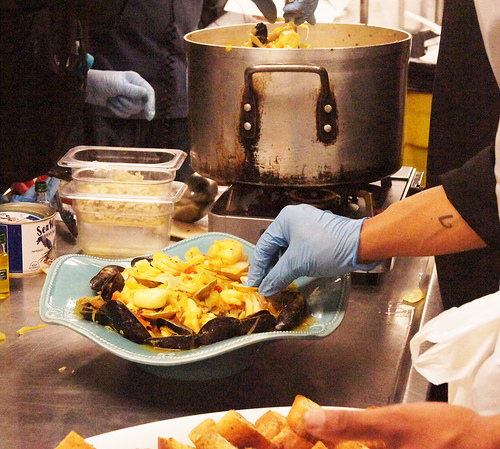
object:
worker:
[254, 139, 499, 448]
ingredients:
[0, 202, 57, 279]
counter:
[0, 184, 435, 444]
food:
[97, 203, 144, 226]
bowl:
[37, 230, 352, 382]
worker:
[245, 0, 499, 444]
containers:
[59, 144, 189, 194]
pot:
[178, 18, 430, 188]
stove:
[206, 164, 423, 273]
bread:
[157, 435, 196, 447]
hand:
[252, 0, 317, 26]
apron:
[408, 291, 499, 418]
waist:
[432, 251, 499, 308]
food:
[273, 286, 307, 330]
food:
[89, 265, 126, 301]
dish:
[37, 230, 351, 382]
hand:
[87, 69, 155, 122]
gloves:
[87, 68, 158, 121]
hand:
[247, 202, 352, 297]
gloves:
[250, 0, 320, 26]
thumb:
[303, 399, 472, 445]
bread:
[253, 410, 314, 448]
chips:
[243, 286, 265, 316]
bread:
[213, 406, 279, 447]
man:
[245, 0, 499, 447]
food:
[195, 314, 243, 344]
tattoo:
[436, 213, 452, 228]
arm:
[356, 140, 499, 265]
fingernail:
[303, 405, 325, 426]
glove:
[247, 203, 383, 297]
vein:
[415, 224, 446, 246]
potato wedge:
[216, 410, 276, 448]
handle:
[239, 65, 333, 140]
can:
[0, 202, 58, 278]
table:
[0, 166, 447, 446]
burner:
[277, 184, 346, 210]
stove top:
[206, 163, 415, 218]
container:
[60, 180, 188, 257]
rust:
[237, 87, 262, 182]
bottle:
[0, 242, 11, 299]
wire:
[156, 20, 175, 150]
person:
[83, 0, 225, 180]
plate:
[85, 406, 368, 447]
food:
[57, 429, 96, 448]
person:
[247, 141, 500, 448]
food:
[93, 298, 151, 344]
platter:
[40, 250, 323, 383]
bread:
[188, 418, 241, 448]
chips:
[176, 292, 205, 332]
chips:
[133, 259, 173, 287]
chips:
[134, 287, 171, 308]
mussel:
[94, 300, 151, 343]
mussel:
[238, 309, 280, 334]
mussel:
[269, 288, 307, 331]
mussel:
[89, 265, 124, 293]